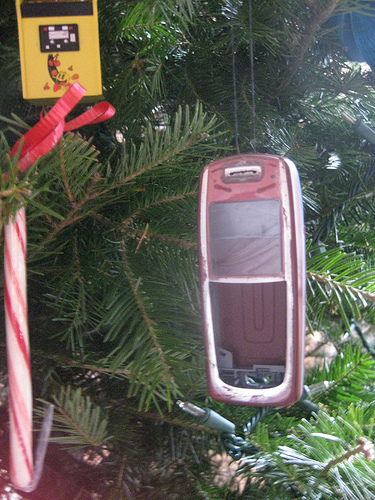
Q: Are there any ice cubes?
A: No, there are no ice cubes.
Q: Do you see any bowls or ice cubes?
A: No, there are no ice cubes or bowls.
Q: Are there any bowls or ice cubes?
A: No, there are no ice cubes or bowls.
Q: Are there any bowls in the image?
A: No, there are no bowls.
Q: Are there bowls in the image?
A: No, there are no bowls.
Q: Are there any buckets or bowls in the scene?
A: No, there are no bowls or buckets.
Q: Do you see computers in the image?
A: No, there are no computers.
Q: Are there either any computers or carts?
A: No, there are no computers or carts.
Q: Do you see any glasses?
A: No, there are no glasses.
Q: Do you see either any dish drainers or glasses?
A: No, there are no glasses or dish drainers.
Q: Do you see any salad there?
A: No, there is no salad.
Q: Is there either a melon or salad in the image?
A: No, there are no salad or melons.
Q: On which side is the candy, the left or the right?
A: The candy is on the left of the image.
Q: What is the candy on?
A: The candy is on the tree.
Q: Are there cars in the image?
A: No, there are no cars.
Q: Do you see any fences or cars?
A: No, there are no cars or fences.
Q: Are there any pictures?
A: No, there are no pictures.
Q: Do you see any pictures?
A: No, there are no pictures.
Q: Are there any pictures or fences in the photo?
A: No, there are no pictures or fences.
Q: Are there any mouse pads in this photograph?
A: No, there are no mouse pads.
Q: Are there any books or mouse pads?
A: No, there are no mouse pads or books.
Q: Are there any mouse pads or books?
A: No, there are no mouse pads or books.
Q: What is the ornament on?
A: The ornament is on the tree.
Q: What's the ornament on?
A: The ornament is on the tree.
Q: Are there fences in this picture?
A: No, there are no fences.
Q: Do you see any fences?
A: No, there are no fences.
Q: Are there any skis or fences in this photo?
A: No, there are no fences or skis.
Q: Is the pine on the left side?
A: Yes, the pine is on the left of the image.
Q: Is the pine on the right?
A: No, the pine is on the left of the image.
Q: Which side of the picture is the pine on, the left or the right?
A: The pine is on the left of the image.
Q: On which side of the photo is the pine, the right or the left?
A: The pine is on the left of the image.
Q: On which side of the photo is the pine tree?
A: The pine tree is on the left of the image.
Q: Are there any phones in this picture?
A: Yes, there is a phone.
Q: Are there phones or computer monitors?
A: Yes, there is a phone.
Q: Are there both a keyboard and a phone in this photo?
A: No, there is a phone but no keyboards.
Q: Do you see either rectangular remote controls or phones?
A: Yes, there is a rectangular phone.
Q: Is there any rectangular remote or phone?
A: Yes, there is a rectangular phone.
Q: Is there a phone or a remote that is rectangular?
A: Yes, the phone is rectangular.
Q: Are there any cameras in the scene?
A: No, there are no cameras.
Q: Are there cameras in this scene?
A: No, there are no cameras.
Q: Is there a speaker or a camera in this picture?
A: No, there are no cameras or speakers.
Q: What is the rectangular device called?
A: The device is a phone.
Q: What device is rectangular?
A: The device is a phone.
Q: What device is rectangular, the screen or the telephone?
A: The telephone is rectangular.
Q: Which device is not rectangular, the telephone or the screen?
A: The screen is not rectangular.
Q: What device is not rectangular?
A: The device is a screen.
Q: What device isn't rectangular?
A: The device is a screen.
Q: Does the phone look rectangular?
A: Yes, the phone is rectangular.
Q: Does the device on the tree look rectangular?
A: Yes, the phone is rectangular.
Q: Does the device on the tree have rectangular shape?
A: Yes, the phone is rectangular.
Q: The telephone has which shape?
A: The telephone is rectangular.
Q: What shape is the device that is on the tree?
A: The telephone is rectangular.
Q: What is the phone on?
A: The phone is on the tree.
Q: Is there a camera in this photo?
A: No, there are no cameras.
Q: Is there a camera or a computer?
A: No, there are no cameras or computers.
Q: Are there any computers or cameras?
A: No, there are no cameras or computers.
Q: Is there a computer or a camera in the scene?
A: No, there are no cameras or computers.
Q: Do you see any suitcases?
A: No, there are no suitcases.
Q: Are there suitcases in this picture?
A: No, there are no suitcases.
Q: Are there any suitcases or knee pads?
A: No, there are no suitcases or knee pads.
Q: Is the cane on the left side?
A: Yes, the cane is on the left of the image.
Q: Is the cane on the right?
A: No, the cane is on the left of the image.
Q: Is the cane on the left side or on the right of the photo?
A: The cane is on the left of the image.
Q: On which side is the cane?
A: The cane is on the left of the image.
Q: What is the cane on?
A: The cane is on the tree.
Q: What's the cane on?
A: The cane is on the tree.